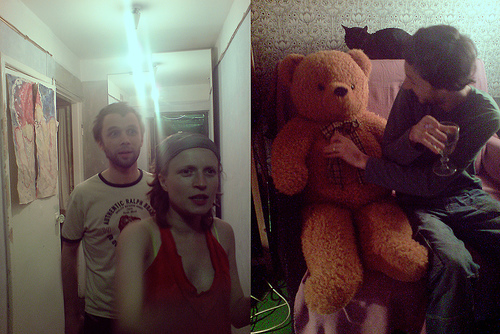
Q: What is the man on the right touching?
A: Teddy bear.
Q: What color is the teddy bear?
A: Brown.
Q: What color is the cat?
A: Black.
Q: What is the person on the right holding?
A: A glass.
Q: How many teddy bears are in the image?
A: One.